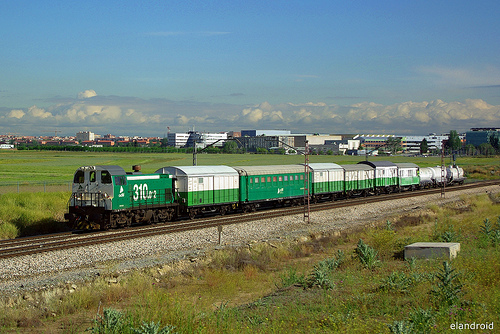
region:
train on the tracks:
[56, 146, 472, 240]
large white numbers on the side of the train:
[126, 180, 153, 202]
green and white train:
[56, 144, 474, 239]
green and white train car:
[159, 160, 241, 213]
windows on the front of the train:
[70, 166, 115, 188]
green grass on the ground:
[6, 144, 496, 331]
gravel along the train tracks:
[0, 174, 499, 271]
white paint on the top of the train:
[311, 162, 346, 182]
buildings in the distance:
[6, 125, 499, 157]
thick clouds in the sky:
[5, 92, 499, 133]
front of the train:
[66, 165, 171, 223]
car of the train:
[220, 155, 305, 190]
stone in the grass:
[395, 226, 455, 256]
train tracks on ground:
[115, 225, 166, 236]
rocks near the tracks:
[5, 255, 57, 281]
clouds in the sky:
[61, 101, 126, 121]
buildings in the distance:
[212, 131, 283, 156]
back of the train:
[407, 161, 462, 183]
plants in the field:
[285, 251, 353, 291]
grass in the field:
[246, 301, 289, 319]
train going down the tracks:
[60, 150, 465, 230]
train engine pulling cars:
[62, 163, 182, 230]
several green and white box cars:
[167, 162, 420, 200]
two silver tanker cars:
[420, 162, 465, 191]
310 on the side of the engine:
[130, 183, 151, 203]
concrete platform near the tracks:
[401, 236, 461, 266]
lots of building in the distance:
[0, 127, 493, 155]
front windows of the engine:
[70, 167, 116, 187]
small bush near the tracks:
[340, 239, 382, 275]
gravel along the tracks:
[3, 180, 495, 287]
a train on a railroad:
[0, 153, 477, 253]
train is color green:
[64, 156, 468, 218]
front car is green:
[68, 160, 183, 229]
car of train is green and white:
[168, 161, 239, 216]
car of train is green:
[237, 159, 313, 207]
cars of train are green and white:
[314, 154, 423, 196]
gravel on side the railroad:
[0, 219, 267, 282]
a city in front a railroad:
[3, 123, 463, 154]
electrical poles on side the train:
[297, 136, 315, 226]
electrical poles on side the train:
[436, 145, 449, 205]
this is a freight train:
[54, 136, 498, 235]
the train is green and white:
[62, 124, 484, 222]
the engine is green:
[50, 138, 186, 228]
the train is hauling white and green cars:
[50, 116, 497, 226]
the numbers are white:
[112, 175, 168, 206]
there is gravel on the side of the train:
[3, 145, 498, 247]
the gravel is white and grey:
[1, 156, 495, 285]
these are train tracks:
[0, 178, 498, 260]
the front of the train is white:
[60, 155, 160, 235]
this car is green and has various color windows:
[237, 151, 317, 223]